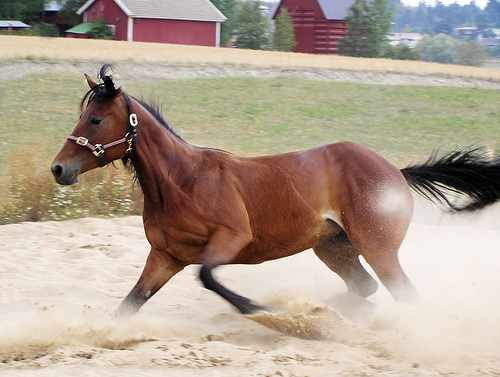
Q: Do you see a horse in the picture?
A: Yes, there is a horse.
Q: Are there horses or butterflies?
A: Yes, there is a horse.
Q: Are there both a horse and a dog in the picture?
A: No, there is a horse but no dogs.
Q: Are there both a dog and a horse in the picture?
A: No, there is a horse but no dogs.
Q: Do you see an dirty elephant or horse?
A: Yes, there is a dirty horse.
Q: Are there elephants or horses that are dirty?
A: Yes, the horse is dirty.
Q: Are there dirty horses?
A: Yes, there is a dirty horse.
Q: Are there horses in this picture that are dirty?
A: Yes, there is a horse that is dirty.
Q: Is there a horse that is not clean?
A: Yes, there is a dirty horse.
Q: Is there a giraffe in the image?
A: No, there are no giraffes.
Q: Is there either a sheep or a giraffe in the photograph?
A: No, there are no giraffes or sheep.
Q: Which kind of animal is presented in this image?
A: The animal is a horse.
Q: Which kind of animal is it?
A: The animal is a horse.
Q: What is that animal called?
A: This is a horse.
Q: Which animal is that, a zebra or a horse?
A: This is a horse.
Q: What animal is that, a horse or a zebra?
A: This is a horse.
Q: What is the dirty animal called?
A: The animal is a horse.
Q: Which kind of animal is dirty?
A: The animal is a horse.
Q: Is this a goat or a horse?
A: This is a horse.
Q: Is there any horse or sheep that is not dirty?
A: No, there is a horse but it is dirty.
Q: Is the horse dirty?
A: Yes, the horse is dirty.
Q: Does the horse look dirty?
A: Yes, the horse is dirty.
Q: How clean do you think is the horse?
A: The horse is dirty.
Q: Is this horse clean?
A: No, the horse is dirty.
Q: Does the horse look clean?
A: No, the horse is dirty.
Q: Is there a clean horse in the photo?
A: No, there is a horse but it is dirty.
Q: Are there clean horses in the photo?
A: No, there is a horse but it is dirty.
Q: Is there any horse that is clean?
A: No, there is a horse but it is dirty.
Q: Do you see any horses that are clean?
A: No, there is a horse but it is dirty.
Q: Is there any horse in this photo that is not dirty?
A: No, there is a horse but it is dirty.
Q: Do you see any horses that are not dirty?
A: No, there is a horse but it is dirty.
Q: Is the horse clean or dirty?
A: The horse is dirty.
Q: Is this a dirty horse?
A: Yes, this is a dirty horse.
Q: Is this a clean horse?
A: No, this is a dirty horse.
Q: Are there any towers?
A: No, there are no towers.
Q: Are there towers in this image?
A: No, there are no towers.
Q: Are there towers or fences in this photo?
A: No, there are no towers or fences.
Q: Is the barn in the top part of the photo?
A: Yes, the barn is in the top of the image.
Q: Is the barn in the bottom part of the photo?
A: No, the barn is in the top of the image.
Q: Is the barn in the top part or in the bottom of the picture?
A: The barn is in the top of the image.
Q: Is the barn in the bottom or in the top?
A: The barn is in the top of the image.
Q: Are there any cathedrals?
A: No, there are no cathedrals.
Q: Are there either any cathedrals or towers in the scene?
A: No, there are no cathedrals or towers.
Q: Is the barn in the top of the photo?
A: Yes, the barn is in the top of the image.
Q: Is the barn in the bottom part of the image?
A: No, the barn is in the top of the image.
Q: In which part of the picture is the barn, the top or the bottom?
A: The barn is in the top of the image.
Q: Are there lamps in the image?
A: No, there are no lamps.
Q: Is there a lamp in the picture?
A: No, there are no lamps.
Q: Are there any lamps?
A: No, there are no lamps.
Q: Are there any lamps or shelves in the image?
A: No, there are no lamps or shelves.